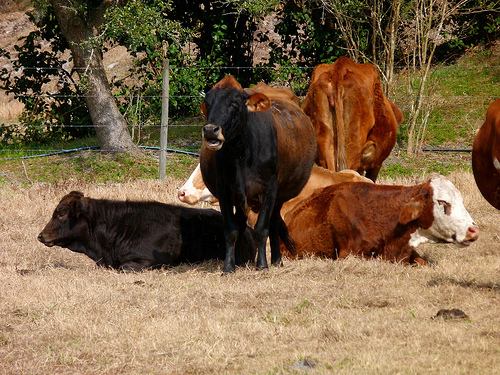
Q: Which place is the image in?
A: It is at the field.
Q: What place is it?
A: It is a field.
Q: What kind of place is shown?
A: It is a field.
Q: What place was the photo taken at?
A: It was taken at the field.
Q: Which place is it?
A: It is a field.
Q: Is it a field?
A: Yes, it is a field.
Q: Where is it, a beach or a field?
A: It is a field.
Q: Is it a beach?
A: No, it is a field.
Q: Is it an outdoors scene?
A: Yes, it is outdoors.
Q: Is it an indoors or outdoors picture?
A: It is outdoors.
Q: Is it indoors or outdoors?
A: It is outdoors.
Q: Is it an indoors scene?
A: No, it is outdoors.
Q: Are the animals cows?
A: Yes, all the animals are cows.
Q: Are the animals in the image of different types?
A: No, all the animals are cows.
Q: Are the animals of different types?
A: No, all the animals are cows.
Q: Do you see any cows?
A: Yes, there is a cow.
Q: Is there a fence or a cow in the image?
A: Yes, there is a cow.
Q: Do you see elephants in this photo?
A: No, there are no elephants.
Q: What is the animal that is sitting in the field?
A: The animal is a cow.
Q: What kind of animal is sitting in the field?
A: The animal is a cow.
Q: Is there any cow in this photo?
A: Yes, there is a cow.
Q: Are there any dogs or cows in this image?
A: Yes, there is a cow.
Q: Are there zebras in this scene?
A: No, there are no zebras.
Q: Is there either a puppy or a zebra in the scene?
A: No, there are no zebras or puppies.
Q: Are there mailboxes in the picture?
A: No, there are no mailboxes.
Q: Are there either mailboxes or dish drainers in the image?
A: No, there are no mailboxes or dish drainers.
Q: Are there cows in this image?
A: Yes, there is a cow.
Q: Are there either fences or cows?
A: Yes, there is a cow.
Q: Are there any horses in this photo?
A: No, there are no horses.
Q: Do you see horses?
A: No, there are no horses.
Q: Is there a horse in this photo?
A: No, there are no horses.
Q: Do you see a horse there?
A: No, there are no horses.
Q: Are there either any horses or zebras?
A: No, there are no horses or zebras.